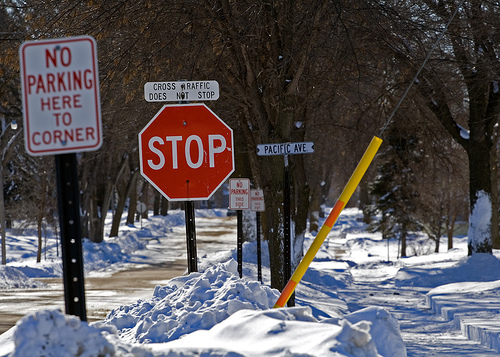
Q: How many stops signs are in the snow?
A: 1.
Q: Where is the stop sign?
A: Under the cross traffic sign.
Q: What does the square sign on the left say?
A: No parking here to corner.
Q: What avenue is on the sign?
A: Pacific Ave.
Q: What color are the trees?
A: Brown.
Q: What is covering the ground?
A: Snow.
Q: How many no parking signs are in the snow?
A: 3.